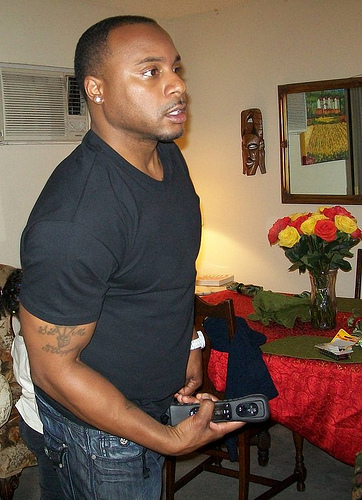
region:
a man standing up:
[28, 28, 338, 496]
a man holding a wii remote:
[28, 4, 358, 472]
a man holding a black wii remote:
[13, 15, 316, 491]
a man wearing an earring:
[22, 15, 295, 314]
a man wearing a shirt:
[11, 5, 287, 372]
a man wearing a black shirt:
[42, 7, 303, 363]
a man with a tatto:
[11, 5, 351, 430]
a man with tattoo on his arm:
[39, 10, 342, 373]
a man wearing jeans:
[20, 25, 293, 495]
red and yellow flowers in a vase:
[261, 197, 360, 327]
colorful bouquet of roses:
[263, 199, 361, 333]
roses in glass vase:
[263, 203, 361, 340]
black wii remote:
[164, 393, 273, 435]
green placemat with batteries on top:
[259, 323, 360, 365]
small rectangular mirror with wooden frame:
[269, 77, 359, 209]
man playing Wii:
[10, 6, 250, 498]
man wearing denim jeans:
[18, 12, 246, 497]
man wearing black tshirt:
[14, 4, 229, 497]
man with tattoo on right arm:
[10, 5, 233, 498]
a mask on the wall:
[236, 105, 270, 179]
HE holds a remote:
[161, 389, 271, 432]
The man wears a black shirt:
[17, 126, 208, 438]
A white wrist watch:
[185, 312, 207, 354]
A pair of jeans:
[27, 414, 163, 498]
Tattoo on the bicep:
[30, 305, 87, 364]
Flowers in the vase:
[268, 194, 361, 322]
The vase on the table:
[296, 270, 347, 342]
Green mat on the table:
[255, 321, 359, 370]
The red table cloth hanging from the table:
[269, 358, 348, 470]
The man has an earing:
[84, 72, 107, 112]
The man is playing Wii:
[141, 386, 284, 438]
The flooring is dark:
[175, 454, 343, 496]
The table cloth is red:
[254, 347, 347, 409]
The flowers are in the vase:
[260, 212, 359, 281]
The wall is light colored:
[223, 169, 272, 263]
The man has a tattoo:
[27, 303, 105, 366]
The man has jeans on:
[32, 397, 175, 498]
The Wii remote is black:
[154, 392, 288, 440]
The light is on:
[190, 215, 267, 292]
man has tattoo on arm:
[12, 297, 100, 390]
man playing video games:
[18, 47, 286, 464]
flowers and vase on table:
[269, 194, 358, 339]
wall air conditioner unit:
[1, 57, 101, 151]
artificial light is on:
[186, 170, 257, 307]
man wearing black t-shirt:
[12, 9, 214, 434]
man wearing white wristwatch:
[180, 314, 208, 361]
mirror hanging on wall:
[266, 69, 361, 211]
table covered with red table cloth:
[219, 289, 360, 391]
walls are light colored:
[182, 11, 360, 305]